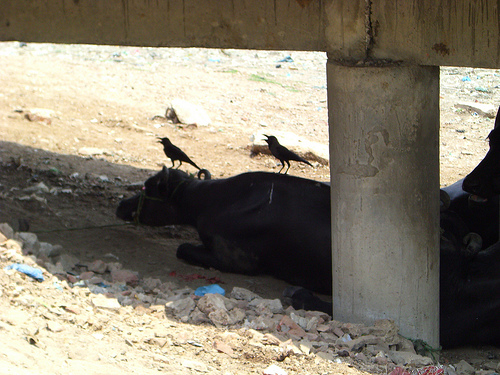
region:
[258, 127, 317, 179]
bird on top of a cow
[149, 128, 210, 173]
bird on top of a cow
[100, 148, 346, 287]
cow lying under a bridge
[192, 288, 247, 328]
rock lying on the ground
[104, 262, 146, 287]
rock lying on the ground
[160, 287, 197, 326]
rock lying on the ground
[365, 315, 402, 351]
rock lying on the ground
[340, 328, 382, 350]
rock lying on the ground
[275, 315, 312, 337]
rock lying on the ground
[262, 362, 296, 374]
rock lying on the ground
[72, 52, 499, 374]
a cow laying down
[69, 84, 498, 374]
a cow undere a bridge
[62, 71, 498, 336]
a black cow laying down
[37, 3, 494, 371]
a black cow laying under bridge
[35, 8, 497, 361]
a cow laying in the shade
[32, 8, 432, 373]
a black cow laying in the shade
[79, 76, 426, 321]
birds on a cow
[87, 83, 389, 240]
two birds on a cow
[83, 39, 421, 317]
a cow with birds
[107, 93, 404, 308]
a cow with two birds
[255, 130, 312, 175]
Blackbird on cow body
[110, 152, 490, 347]
Cow lying on rocks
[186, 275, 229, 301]
Blue trash on ground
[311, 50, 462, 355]
Round cement support column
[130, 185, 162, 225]
Bridle on cow's head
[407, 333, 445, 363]
Green plant near column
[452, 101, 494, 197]
Head of brown cow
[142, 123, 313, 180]
Two singing black birds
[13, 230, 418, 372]
Rocks piled near cows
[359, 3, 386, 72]
Crack in bridge frame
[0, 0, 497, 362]
Underside of a cement bridge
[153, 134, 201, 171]
A black bird cawing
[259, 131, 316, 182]
A black bird standing on a cow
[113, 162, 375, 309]
A black cow laying under a cement bridge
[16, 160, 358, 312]
A black cow tied to a stake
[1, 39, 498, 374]
Arid rocky landscape with sparse vegetation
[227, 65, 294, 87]
Patch of sparse vegetation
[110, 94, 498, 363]
Cows laying under a bridge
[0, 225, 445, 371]
Pile or rubble and blue plastic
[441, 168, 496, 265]
The tire of a car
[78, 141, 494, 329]
dog laying under a pier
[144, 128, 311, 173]
black birds on the ground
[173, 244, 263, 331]
blue trash laying on the ground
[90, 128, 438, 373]
dog is laying in the shade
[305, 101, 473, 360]
large, round wooden pillar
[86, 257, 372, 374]
lots of rocks on the ground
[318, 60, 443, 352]
the pillar is concrete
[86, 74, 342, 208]
it is sunny beyond the overhang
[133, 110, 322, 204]
the birds have their mouths open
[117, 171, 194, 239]
dog has a harness on his mouth